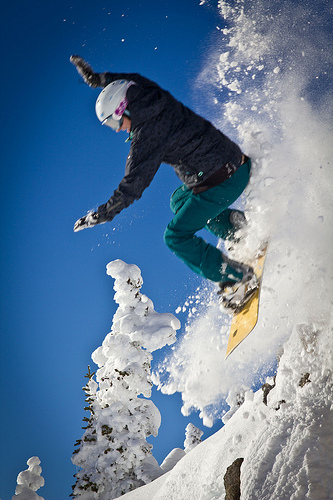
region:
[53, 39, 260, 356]
Someone doing a snowboarding trick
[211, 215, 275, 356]
Tan wooden snowboard floating in air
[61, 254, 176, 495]
A pine tree covered in snow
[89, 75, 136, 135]
White snowboarding helmet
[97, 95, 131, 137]
White goggles with pink strap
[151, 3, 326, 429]
Snow powder kicked up by snowboarder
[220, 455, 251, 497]
Piece of rock sticking out through snow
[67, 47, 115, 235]
Pair of black winter snow gloves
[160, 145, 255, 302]
Green snow pants with snow on the bottom of each leg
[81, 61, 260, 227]
Black down snow jacket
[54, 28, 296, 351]
man snow boarding down hill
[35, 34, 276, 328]
man on top of snow board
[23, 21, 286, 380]
man riding a snow board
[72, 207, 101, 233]
black and white snow glove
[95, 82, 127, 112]
white snow helmet on head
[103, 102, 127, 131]
purple and blue snow goggles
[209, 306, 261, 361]
brown colored snow board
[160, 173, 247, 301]
blue snow pants on man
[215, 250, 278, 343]
wahite boot and yellow board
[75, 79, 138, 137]
helmet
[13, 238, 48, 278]
white clouds in blue sky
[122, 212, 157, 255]
white clouds in blue sky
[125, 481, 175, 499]
White snow covering the ground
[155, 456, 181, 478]
White snow covering the ground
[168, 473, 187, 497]
White snow covering the ground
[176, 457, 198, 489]
White snow covering the ground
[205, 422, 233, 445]
White snow covering the ground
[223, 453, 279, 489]
White snow covering the ground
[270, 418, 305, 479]
White snow covering the ground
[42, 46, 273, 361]
snow boarder in snow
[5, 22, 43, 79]
white clouds in blue sky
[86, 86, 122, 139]
white helmet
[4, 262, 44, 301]
white clouds in blue sky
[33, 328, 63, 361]
white clouds in blue sky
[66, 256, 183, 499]
a snow covered pine tree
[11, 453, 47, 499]
a snow covered pine tree